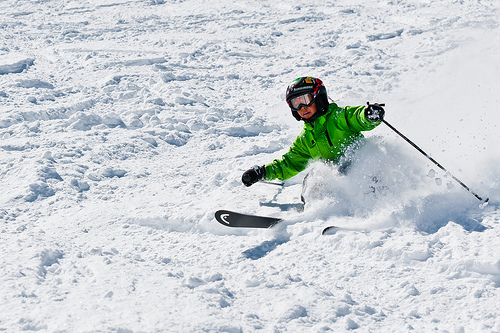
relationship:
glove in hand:
[369, 93, 386, 130] [362, 104, 385, 124]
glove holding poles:
[369, 93, 386, 130] [378, 118, 490, 203]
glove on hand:
[240, 163, 268, 187] [240, 166, 264, 188]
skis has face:
[214, 209, 369, 234] [289, 90, 318, 120]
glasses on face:
[286, 85, 321, 112] [289, 90, 318, 120]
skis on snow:
[214, 209, 369, 234] [58, 258, 465, 320]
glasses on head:
[286, 87, 321, 111] [282, 75, 331, 120]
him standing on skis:
[241, 76, 386, 206] [216, 209, 368, 234]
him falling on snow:
[241, 76, 386, 206] [95, 231, 487, 331]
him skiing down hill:
[241, 76, 386, 206] [2, 1, 499, 331]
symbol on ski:
[216, 208, 233, 225] [214, 209, 284, 228]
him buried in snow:
[241, 76, 386, 206] [0, 2, 498, 327]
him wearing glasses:
[241, 76, 386, 206] [286, 87, 321, 111]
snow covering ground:
[0, 2, 498, 327] [3, 1, 497, 328]